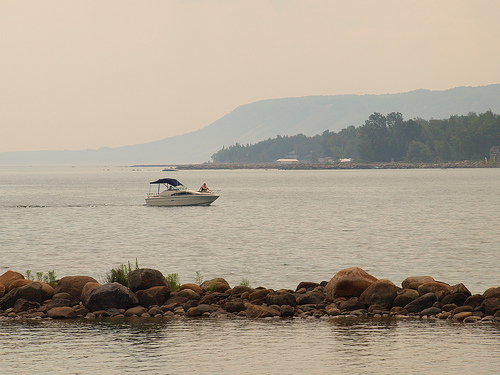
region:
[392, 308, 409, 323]
part of a rock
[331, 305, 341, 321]
edge of a rock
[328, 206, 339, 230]
part of an ocean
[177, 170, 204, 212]
part of a boat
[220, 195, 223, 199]
tip of a boat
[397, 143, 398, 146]
part of a forest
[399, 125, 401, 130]
edge of a forest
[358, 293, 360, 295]
edge of a rock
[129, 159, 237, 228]
small boat in bay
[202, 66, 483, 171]
mountains in the distance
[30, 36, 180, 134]
overcast sky above mountains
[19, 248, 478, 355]
rock jetty in bay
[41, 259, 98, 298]
brown rocks on jetty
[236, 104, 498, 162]
thick forest on land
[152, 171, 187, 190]
canvas top on boat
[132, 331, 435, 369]
reflections of rocks in water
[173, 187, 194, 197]
small windows on boat cabin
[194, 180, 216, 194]
person on front of boat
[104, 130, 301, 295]
a boat in the water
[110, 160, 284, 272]
a boat on the water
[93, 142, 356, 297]
a boat on a body of water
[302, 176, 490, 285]
a body of water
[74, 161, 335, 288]
a boat in a body of water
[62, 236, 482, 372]
rocks in a body of water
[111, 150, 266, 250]
a person on a boat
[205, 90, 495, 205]
a island in the middle of the water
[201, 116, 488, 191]
a island on the body of water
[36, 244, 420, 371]
different sized rocks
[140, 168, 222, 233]
boat on the water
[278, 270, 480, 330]
rocks in the water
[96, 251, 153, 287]
grass in the rocks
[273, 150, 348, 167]
cars on road by water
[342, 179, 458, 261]
calm waters in the ocean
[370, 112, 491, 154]
green trees on the land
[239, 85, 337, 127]
mountains in the distance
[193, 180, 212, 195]
man on a boat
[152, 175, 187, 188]
canopy on a boat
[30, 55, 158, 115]
hazy sky in the distance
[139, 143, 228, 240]
Boat in the water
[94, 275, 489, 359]
Wall of rocks in the water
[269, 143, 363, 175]
Home located on shore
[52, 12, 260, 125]
It is cloudy and foggy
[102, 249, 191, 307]
Grass growing in between the rocks.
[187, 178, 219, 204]
Person on front of boat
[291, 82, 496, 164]
Trees growing on the shore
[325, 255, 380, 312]
Large rock mixed in with small ones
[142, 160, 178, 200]
Top on the boat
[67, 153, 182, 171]
Rocks in the water